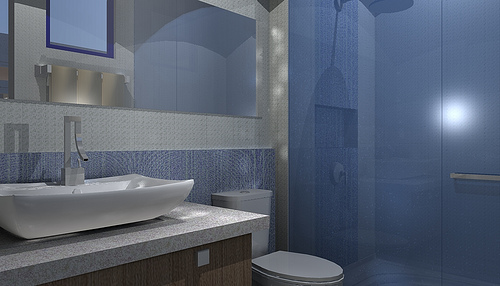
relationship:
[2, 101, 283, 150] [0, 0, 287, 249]
stripe on wall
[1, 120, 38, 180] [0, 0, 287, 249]
shadow on wall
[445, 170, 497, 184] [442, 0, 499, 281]
bar on door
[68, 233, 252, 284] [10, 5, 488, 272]
wood sink on bathroom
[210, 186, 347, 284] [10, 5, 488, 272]
toilet in bathroom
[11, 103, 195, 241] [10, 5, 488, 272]
sink in bathroom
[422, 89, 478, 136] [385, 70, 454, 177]
glare on wall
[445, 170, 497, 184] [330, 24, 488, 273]
bar in shower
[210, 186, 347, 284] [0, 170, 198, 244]
toilet next sink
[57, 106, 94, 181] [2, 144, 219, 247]
faucet on sink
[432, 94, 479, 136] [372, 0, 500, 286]
glare on bathroom walls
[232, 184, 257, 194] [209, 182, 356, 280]
button on toilet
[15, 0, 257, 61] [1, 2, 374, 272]
shadow casted on wall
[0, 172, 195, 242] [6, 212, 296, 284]
sink sitting on top of vanity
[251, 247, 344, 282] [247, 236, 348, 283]
lid covering toilet seat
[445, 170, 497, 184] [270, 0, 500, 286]
bar mounted on door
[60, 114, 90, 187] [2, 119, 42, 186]
faucet casting shadow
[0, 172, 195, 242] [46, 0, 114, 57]
sink sitting below window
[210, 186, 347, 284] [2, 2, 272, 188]
toilet sitting against wall